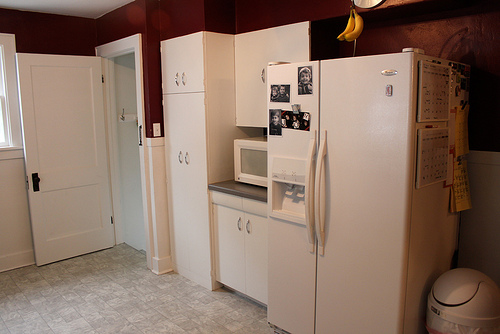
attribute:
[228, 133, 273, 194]
microwave — white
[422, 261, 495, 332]
trash can — white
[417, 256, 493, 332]
trash can — white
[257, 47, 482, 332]
refrigerator — white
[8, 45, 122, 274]
door — white, open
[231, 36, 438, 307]
fridge — white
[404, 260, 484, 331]
can — white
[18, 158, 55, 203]
knob — black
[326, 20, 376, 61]
bananas — yellow 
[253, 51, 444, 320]
refrigerator — white 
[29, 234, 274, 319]
floor — white , grey 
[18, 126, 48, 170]
handle — Dark 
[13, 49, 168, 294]
door — white 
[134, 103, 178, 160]
switch — white 